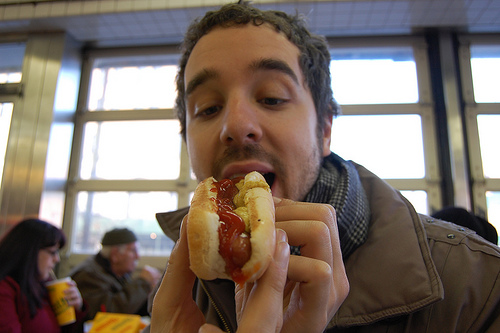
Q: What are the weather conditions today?
A: It is clear.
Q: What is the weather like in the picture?
A: It is clear.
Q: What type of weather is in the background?
A: It is clear.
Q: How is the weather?
A: It is clear.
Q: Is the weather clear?
A: Yes, it is clear.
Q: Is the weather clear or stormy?
A: It is clear.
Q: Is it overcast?
A: No, it is clear.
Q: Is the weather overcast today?
A: No, it is clear.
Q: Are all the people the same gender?
A: No, they are both male and female.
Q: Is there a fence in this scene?
A: No, there are no fences.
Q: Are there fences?
A: No, there are no fences.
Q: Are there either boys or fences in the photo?
A: No, there are no fences or boys.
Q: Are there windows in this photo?
A: Yes, there is a window.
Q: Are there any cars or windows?
A: Yes, there is a window.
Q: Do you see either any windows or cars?
A: Yes, there is a window.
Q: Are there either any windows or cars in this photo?
A: Yes, there is a window.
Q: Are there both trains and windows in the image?
A: No, there is a window but no trains.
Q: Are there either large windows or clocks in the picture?
A: Yes, there is a large window.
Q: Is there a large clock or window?
A: Yes, there is a large window.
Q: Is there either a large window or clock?
A: Yes, there is a large window.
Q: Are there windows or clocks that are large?
A: Yes, the window is large.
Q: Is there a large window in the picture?
A: Yes, there is a large window.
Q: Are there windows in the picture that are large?
A: Yes, there is a window that is large.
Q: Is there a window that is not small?
A: Yes, there is a large window.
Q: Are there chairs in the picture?
A: No, there are no chairs.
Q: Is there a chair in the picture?
A: No, there are no chairs.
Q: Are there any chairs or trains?
A: No, there are no chairs or trains.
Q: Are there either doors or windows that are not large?
A: No, there is a window but it is large.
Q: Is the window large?
A: Yes, the window is large.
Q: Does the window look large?
A: Yes, the window is large.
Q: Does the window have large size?
A: Yes, the window is large.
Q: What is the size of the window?
A: The window is large.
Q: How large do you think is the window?
A: The window is large.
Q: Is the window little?
A: No, the window is large.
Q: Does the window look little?
A: No, the window is large.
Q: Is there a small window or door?
A: No, there is a window but it is large.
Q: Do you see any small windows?
A: No, there is a window but it is large.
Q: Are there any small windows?
A: No, there is a window but it is large.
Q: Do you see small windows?
A: No, there is a window but it is large.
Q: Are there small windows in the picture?
A: No, there is a window but it is large.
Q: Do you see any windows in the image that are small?
A: No, there is a window but it is large.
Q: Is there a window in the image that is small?
A: No, there is a window but it is large.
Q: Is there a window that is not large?
A: No, there is a window but it is large.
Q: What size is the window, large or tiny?
A: The window is large.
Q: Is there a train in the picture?
A: No, there are no trains.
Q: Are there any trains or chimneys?
A: No, there are no trains or chimneys.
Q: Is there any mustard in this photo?
A: Yes, there is mustard.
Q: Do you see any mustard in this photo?
A: Yes, there is mustard.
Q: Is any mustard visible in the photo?
A: Yes, there is mustard.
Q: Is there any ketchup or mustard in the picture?
A: Yes, there is mustard.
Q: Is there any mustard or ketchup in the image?
A: Yes, there is mustard.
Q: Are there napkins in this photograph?
A: No, there are no napkins.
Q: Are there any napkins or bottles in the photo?
A: No, there are no napkins or bottles.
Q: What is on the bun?
A: The mustard is on the bun.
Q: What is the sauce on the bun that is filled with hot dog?
A: The sauce is mustard.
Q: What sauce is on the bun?
A: The sauce is mustard.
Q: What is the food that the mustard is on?
A: The food is a bun.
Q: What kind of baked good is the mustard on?
A: The mustard is on the bun.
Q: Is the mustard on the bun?
A: Yes, the mustard is on the bun.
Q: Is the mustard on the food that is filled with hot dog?
A: Yes, the mustard is on the bun.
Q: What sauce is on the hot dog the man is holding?
A: The sauce is mustard.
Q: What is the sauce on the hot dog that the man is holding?
A: The sauce is mustard.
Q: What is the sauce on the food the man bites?
A: The sauce is mustard.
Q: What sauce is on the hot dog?
A: The sauce is mustard.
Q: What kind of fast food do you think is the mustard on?
A: The mustard is on the hot dog.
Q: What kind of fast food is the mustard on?
A: The mustard is on the hot dog.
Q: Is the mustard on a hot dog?
A: Yes, the mustard is on a hot dog.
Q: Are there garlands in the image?
A: No, there are no garlands.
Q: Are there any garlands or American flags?
A: No, there are no garlands or American flags.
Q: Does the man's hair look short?
A: Yes, the hair is short.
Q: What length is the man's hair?
A: The hair is short.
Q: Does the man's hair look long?
A: No, the hair is short.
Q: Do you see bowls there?
A: No, there are no bowls.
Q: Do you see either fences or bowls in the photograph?
A: No, there are no bowls or fences.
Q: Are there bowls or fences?
A: No, there are no bowls or fences.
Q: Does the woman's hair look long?
A: Yes, the hair is long.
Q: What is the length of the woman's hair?
A: The hair is long.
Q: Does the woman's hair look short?
A: No, the hair is long.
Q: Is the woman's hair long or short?
A: The hair is long.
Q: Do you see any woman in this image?
A: Yes, there is a woman.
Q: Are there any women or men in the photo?
A: Yes, there is a woman.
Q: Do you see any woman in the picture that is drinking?
A: Yes, there is a woman that is drinking.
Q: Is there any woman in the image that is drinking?
A: Yes, there is a woman that is drinking.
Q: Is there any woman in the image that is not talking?
A: Yes, there is a woman that is drinking.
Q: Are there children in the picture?
A: No, there are no children.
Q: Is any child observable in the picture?
A: No, there are no children.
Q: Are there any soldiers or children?
A: No, there are no children or soldiers.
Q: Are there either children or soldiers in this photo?
A: No, there are no children or soldiers.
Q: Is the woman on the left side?
A: Yes, the woman is on the left of the image.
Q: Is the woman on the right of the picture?
A: No, the woman is on the left of the image.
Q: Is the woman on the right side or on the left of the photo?
A: The woman is on the left of the image.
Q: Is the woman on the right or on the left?
A: The woman is on the left of the image.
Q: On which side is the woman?
A: The woman is on the left of the image.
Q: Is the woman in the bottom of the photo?
A: Yes, the woman is in the bottom of the image.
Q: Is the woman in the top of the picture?
A: No, the woman is in the bottom of the image.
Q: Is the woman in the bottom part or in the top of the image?
A: The woman is in the bottom of the image.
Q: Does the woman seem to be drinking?
A: Yes, the woman is drinking.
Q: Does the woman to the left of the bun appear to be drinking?
A: Yes, the woman is drinking.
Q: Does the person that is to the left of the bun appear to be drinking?
A: Yes, the woman is drinking.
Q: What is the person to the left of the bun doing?
A: The woman is drinking.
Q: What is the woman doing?
A: The woman is drinking.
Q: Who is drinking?
A: The woman is drinking.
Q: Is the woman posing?
A: No, the woman is drinking.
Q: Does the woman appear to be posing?
A: No, the woman is drinking.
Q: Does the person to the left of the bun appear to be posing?
A: No, the woman is drinking.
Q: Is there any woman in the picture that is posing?
A: No, there is a woman but she is drinking.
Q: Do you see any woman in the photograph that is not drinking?
A: No, there is a woman but she is drinking.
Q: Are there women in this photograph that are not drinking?
A: No, there is a woman but she is drinking.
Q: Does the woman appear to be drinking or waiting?
A: The woman is drinking.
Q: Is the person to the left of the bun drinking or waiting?
A: The woman is drinking.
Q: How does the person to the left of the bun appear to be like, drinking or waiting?
A: The woman is drinking.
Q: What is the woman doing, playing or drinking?
A: The woman is drinking.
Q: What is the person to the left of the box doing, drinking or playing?
A: The woman is drinking.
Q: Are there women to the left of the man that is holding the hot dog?
A: Yes, there is a woman to the left of the man.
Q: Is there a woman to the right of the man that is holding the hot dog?
A: No, the woman is to the left of the man.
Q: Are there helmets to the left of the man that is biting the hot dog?
A: No, there is a woman to the left of the man.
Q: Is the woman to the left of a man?
A: Yes, the woman is to the left of a man.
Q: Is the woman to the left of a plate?
A: No, the woman is to the left of a man.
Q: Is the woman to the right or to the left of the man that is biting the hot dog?
A: The woman is to the left of the man.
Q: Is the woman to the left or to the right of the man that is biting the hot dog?
A: The woman is to the left of the man.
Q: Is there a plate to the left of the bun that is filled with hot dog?
A: No, there is a woman to the left of the bun.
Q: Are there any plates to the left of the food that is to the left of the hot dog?
A: No, there is a woman to the left of the bun.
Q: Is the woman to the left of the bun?
A: Yes, the woman is to the left of the bun.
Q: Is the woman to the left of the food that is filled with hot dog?
A: Yes, the woman is to the left of the bun.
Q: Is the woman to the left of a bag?
A: No, the woman is to the left of the bun.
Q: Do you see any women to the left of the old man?
A: Yes, there is a woman to the left of the man.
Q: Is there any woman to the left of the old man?
A: Yes, there is a woman to the left of the man.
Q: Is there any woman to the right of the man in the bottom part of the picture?
A: No, the woman is to the left of the man.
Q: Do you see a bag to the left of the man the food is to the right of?
A: No, there is a woman to the left of the man.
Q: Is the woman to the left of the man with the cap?
A: Yes, the woman is to the left of the man.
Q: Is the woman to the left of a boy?
A: No, the woman is to the left of the man.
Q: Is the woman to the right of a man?
A: No, the woman is to the left of a man.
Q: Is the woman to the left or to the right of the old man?
A: The woman is to the left of the man.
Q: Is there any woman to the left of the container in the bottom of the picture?
A: Yes, there is a woman to the left of the box.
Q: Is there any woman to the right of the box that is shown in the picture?
A: No, the woman is to the left of the box.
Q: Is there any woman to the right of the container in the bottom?
A: No, the woman is to the left of the box.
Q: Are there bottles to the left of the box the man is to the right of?
A: No, there is a woman to the left of the box.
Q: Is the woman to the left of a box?
A: Yes, the woman is to the left of a box.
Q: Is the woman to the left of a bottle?
A: No, the woman is to the left of a box.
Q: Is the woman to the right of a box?
A: No, the woman is to the left of a box.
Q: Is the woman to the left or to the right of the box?
A: The woman is to the left of the box.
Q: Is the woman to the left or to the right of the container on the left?
A: The woman is to the left of the box.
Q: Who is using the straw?
A: The woman is using the straw.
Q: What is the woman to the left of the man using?
A: The woman is using a straw.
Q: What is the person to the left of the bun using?
A: The woman is using a straw.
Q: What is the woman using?
A: The woman is using a straw.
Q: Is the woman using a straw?
A: Yes, the woman is using a straw.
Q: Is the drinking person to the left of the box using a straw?
A: Yes, the woman is using a straw.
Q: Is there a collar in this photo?
A: Yes, there is a collar.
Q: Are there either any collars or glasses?
A: Yes, there is a collar.